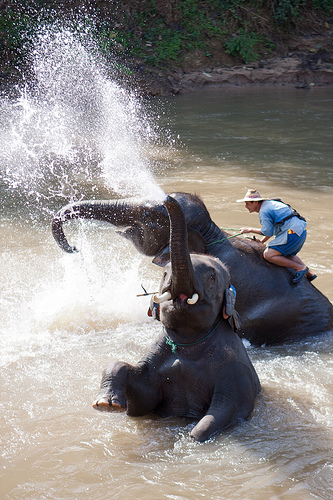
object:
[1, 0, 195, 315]
water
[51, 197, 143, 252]
trunk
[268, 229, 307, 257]
shorts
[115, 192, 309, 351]
elephant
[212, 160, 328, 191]
ripples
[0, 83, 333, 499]
water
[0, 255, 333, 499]
water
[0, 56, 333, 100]
riverside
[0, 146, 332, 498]
water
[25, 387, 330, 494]
ripples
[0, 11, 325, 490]
water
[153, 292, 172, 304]
tusk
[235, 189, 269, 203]
hat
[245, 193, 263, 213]
head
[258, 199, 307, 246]
blue shirt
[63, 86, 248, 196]
water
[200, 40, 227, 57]
ground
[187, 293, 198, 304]
tusk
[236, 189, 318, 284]
man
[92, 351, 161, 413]
leg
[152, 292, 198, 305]
tusks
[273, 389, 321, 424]
ripples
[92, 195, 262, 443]
elephant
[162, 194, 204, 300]
nose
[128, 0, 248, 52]
plant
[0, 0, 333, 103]
terrain